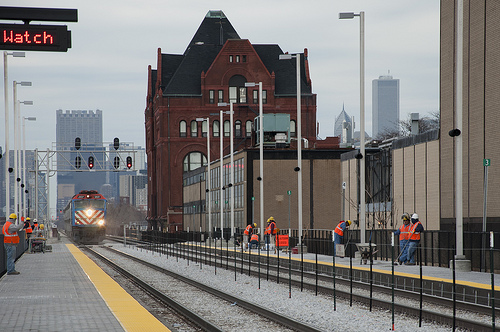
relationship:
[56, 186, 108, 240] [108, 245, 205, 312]
train on tracks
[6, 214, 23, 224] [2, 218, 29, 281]
helmet on man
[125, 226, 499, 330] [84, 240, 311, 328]
poles between tracks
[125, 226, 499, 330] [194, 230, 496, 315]
poles between tracks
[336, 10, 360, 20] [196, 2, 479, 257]
fixtures on poles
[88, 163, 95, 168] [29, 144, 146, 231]
red signal on support structure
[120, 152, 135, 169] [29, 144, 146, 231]
signal on support structure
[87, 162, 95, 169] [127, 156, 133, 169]
red signal on signal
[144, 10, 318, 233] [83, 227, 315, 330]
building beside track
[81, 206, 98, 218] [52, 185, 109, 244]
light on train